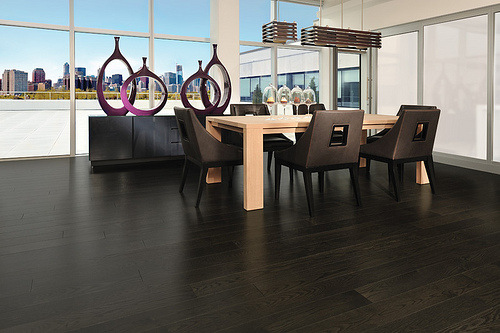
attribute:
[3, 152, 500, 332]
floor — wood, black, dark, hardwood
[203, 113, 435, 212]
table — wooden, white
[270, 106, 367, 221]
chair — black, brown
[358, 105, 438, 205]
chair — brown, black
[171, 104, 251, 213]
chair — brown, black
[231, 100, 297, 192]
chair — brown, black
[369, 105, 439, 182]
chair — brown, black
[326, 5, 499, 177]
wall — glass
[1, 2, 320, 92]
sky — blue, beautiful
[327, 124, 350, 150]
hole — square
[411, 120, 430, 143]
hole — square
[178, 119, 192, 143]
hole — square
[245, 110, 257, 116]
hole — square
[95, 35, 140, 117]
vase — art piece, large, purple, round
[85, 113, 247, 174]
table — dark wood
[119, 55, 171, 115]
vase — art piece, large, purple, round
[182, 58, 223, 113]
vase — art piece, large, purple, round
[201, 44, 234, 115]
vase — art piece, large, purple, round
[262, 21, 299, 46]
light — hanging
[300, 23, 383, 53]
light — hanging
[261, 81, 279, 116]
decoration — glass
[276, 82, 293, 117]
decoration — glass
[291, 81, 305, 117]
decoration — glass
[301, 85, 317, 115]
decoration — glass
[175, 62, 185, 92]
building — tall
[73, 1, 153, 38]
window — glass, large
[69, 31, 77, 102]
post — white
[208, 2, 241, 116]
pillar — white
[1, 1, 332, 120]
wall — transparent